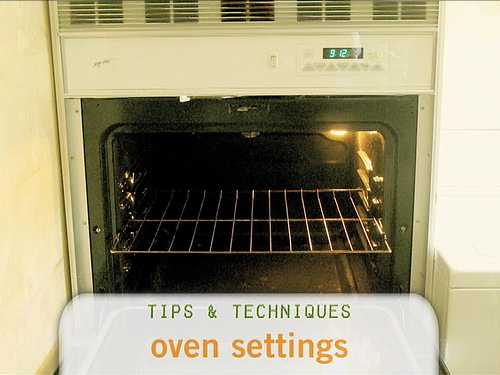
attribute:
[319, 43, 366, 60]
clock — digital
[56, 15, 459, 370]
oven — Open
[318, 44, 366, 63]
display — digital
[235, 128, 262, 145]
light — on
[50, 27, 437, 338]
oven — white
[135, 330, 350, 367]
lettering — Orange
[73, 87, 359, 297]
rack — Metal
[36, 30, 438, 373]
oven — digital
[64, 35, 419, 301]
oven — metal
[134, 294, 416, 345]
text — green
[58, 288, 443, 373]
background — white